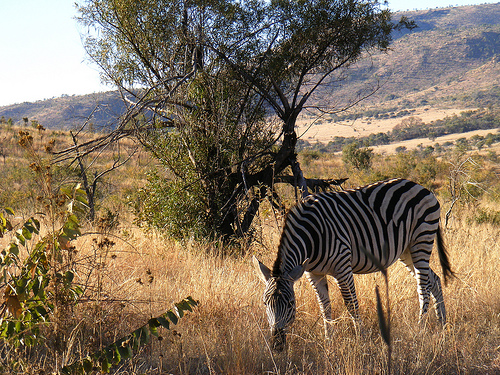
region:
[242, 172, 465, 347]
zebra grazing in field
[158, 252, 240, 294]
brown grass in field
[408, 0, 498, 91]
mountainside covered in rocks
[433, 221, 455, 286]
tail of zebra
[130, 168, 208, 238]
bush with green leaves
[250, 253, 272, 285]
ear of zebra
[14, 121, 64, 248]
brown buds on stem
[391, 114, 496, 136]
tree line on ridge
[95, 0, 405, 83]
tree with green leaves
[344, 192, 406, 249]
black and white stripes on zebra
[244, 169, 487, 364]
zebra in a field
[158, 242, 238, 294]
tall brown grasses in a field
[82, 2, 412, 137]
green leaved tree in a field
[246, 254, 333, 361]
head of a zebra grazing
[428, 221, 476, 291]
tail of a zebra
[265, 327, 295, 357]
nose and mouth of a zebra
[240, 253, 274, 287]
right ear of a zebra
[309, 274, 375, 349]
front legs of a zebra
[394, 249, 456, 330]
back legs of a zebra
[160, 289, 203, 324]
green leaves on a bush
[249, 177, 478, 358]
zebra grazing in field of grass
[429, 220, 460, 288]
black hairy tail of zebra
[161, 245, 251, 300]
field with brown grass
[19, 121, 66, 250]
plant with brown buds on top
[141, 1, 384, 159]
tree with green leaves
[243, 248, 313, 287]
ears of a zebra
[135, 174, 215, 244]
green bush growing beside tree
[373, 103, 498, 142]
line of green trees on mountainside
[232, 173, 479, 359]
A zebra in nature.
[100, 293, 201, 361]
Green leaves on a branch.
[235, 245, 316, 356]
The head of a zebra.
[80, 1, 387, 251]
A tree behind the zebra.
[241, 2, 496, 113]
A mountain in the distance.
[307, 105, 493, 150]
Trees in the disance.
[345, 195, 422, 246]
The zebra has black and white stripes.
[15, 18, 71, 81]
The sky is a very light blue.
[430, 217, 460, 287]
The zebra has a tail.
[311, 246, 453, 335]
The zebra has four legs.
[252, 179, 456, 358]
a black and white zebra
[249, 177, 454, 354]
a zebra with black and white stripes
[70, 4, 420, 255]
a tree with green leaves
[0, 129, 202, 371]
a bush with green leaves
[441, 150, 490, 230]
a dead and bare tree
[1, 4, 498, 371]
an tan open landscape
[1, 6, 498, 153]
a large mountainous background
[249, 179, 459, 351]
a zebra grazing in the grass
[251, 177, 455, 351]
a zebra eating alone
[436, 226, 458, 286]
a bushy zebra tail